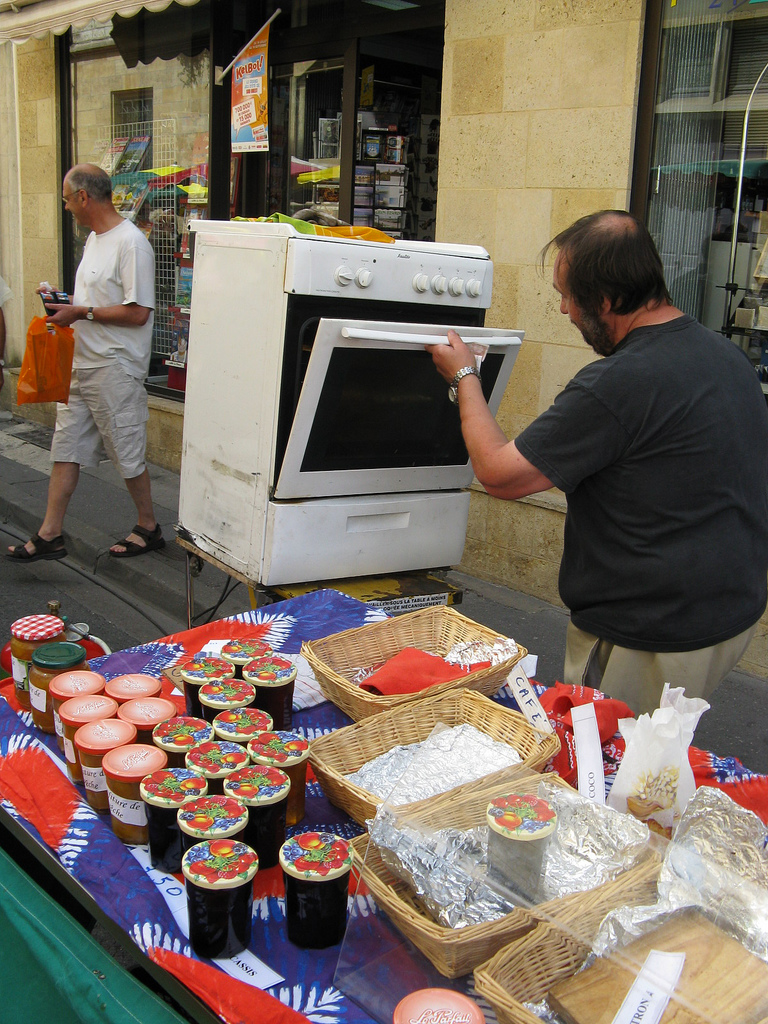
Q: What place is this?
A: It is a sidewalk.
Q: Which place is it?
A: It is a sidewalk.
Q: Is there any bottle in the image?
A: No, there are no bottles.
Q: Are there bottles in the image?
A: No, there are no bottles.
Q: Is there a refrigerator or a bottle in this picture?
A: No, there are no bottles or refrigerators.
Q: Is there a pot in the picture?
A: No, there are no pots.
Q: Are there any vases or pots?
A: No, there are no pots or vases.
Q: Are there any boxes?
A: No, there are no boxes.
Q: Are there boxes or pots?
A: No, there are no boxes or pots.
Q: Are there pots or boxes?
A: No, there are no boxes or pots.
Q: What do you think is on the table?
A: The jar is on the table.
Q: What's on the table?
A: The jar is on the table.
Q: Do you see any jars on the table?
A: Yes, there is a jar on the table.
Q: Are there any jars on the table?
A: Yes, there is a jar on the table.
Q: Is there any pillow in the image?
A: No, there are no pillows.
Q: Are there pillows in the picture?
A: No, there are no pillows.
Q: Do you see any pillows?
A: No, there are no pillows.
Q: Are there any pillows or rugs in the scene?
A: No, there are no pillows or rugs.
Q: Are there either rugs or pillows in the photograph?
A: No, there are no pillows or rugs.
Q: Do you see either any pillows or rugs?
A: No, there are no pillows or rugs.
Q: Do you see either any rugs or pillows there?
A: No, there are no pillows or rugs.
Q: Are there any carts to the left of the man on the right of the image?
A: Yes, there is a cart to the left of the man.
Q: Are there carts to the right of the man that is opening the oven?
A: No, the cart is to the left of the man.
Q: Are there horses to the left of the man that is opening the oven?
A: No, there is a cart to the left of the man.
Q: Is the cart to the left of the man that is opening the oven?
A: Yes, the cart is to the left of the man.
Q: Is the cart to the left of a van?
A: No, the cart is to the left of the man.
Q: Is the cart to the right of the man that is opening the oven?
A: No, the cart is to the left of the man.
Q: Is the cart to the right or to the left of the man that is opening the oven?
A: The cart is to the left of the man.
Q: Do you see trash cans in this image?
A: No, there are no trash cans.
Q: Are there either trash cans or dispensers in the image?
A: No, there are no trash cans or dispensers.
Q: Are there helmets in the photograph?
A: No, there are no helmets.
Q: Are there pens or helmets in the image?
A: No, there are no helmets or pens.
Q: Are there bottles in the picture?
A: No, there are no bottles.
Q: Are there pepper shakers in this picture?
A: No, there are no pepper shakers.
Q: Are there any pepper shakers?
A: No, there are no pepper shakers.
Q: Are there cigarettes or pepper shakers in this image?
A: No, there are no pepper shakers or cigarettes.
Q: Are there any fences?
A: No, there are no fences.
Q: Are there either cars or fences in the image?
A: No, there are no fences or cars.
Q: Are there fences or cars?
A: No, there are no fences or cars.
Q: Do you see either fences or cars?
A: No, there are no fences or cars.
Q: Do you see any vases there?
A: No, there are no vases.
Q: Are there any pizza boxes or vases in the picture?
A: No, there are no vases or pizza boxes.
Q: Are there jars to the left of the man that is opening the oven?
A: Yes, there is a jar to the left of the man.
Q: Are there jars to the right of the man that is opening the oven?
A: No, the jar is to the left of the man.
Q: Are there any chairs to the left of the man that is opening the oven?
A: No, there is a jar to the left of the man.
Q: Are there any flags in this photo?
A: Yes, there is a flag.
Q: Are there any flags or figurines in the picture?
A: Yes, there is a flag.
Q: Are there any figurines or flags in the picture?
A: Yes, there is a flag.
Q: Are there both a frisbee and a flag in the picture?
A: No, there is a flag but no frisbees.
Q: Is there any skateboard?
A: No, there are no skateboards.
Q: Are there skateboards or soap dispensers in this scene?
A: No, there are no skateboards or soap dispensers.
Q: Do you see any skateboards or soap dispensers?
A: No, there are no skateboards or soap dispensers.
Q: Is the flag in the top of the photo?
A: Yes, the flag is in the top of the image.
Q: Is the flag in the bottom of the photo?
A: No, the flag is in the top of the image.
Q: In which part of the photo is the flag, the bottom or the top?
A: The flag is in the top of the image.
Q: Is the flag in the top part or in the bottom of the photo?
A: The flag is in the top of the image.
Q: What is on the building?
A: The flag is on the building.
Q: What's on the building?
A: The flag is on the building.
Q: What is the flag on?
A: The flag is on the building.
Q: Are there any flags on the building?
A: Yes, there is a flag on the building.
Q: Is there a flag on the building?
A: Yes, there is a flag on the building.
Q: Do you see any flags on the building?
A: Yes, there is a flag on the building.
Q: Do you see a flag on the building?
A: Yes, there is a flag on the building.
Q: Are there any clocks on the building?
A: No, there is a flag on the building.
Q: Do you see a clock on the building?
A: No, there is a flag on the building.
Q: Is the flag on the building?
A: Yes, the flag is on the building.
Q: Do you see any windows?
A: Yes, there is a window.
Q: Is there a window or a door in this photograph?
A: Yes, there is a window.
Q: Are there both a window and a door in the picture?
A: Yes, there are both a window and a door.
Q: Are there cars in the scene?
A: No, there are no cars.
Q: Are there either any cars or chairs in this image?
A: No, there are no cars or chairs.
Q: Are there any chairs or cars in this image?
A: No, there are no cars or chairs.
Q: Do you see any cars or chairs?
A: No, there are no cars or chairs.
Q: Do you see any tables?
A: Yes, there is a table.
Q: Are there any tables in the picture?
A: Yes, there is a table.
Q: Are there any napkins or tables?
A: Yes, there is a table.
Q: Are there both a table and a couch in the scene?
A: No, there is a table but no couches.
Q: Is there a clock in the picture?
A: No, there are no clocks.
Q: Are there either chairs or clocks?
A: No, there are no clocks or chairs.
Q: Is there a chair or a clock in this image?
A: No, there are no clocks or chairs.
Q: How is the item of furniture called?
A: The piece of furniture is a table.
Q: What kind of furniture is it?
A: The piece of furniture is a table.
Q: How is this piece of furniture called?
A: This is a table.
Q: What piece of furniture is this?
A: This is a table.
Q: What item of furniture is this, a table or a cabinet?
A: This is a table.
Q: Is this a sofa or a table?
A: This is a table.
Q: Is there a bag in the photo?
A: Yes, there is a bag.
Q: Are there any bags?
A: Yes, there is a bag.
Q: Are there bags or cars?
A: Yes, there is a bag.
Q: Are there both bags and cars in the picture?
A: No, there is a bag but no cars.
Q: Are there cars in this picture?
A: No, there are no cars.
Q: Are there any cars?
A: No, there are no cars.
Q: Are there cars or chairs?
A: No, there are no cars or chairs.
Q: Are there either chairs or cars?
A: No, there are no cars or chairs.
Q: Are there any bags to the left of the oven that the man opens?
A: Yes, there is a bag to the left of the oven.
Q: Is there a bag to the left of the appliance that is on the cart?
A: Yes, there is a bag to the left of the oven.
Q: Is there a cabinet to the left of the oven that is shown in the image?
A: No, there is a bag to the left of the oven.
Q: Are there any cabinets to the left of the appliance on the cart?
A: No, there is a bag to the left of the oven.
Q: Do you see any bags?
A: Yes, there is a bag.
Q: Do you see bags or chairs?
A: Yes, there is a bag.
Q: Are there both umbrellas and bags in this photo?
A: No, there is a bag but no umbrellas.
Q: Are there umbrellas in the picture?
A: No, there are no umbrellas.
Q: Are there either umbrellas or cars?
A: No, there are no umbrellas or cars.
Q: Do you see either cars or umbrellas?
A: No, there are no umbrellas or cars.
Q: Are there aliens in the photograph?
A: No, there are no aliens.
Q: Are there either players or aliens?
A: No, there are no aliens or players.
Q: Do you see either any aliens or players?
A: No, there are no aliens or players.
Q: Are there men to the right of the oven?
A: Yes, there is a man to the right of the oven.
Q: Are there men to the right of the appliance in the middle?
A: Yes, there is a man to the right of the oven.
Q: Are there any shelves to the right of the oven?
A: No, there is a man to the right of the oven.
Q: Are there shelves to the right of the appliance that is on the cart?
A: No, there is a man to the right of the oven.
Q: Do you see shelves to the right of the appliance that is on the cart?
A: No, there is a man to the right of the oven.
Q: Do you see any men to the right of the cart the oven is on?
A: Yes, there is a man to the right of the cart.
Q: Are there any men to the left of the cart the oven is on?
A: No, the man is to the right of the cart.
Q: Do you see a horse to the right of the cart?
A: No, there is a man to the right of the cart.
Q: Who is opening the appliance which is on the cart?
A: The man is opening the oven.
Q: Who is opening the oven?
A: The man is opening the oven.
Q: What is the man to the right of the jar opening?
A: The man is opening the oven.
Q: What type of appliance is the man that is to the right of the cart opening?
A: The man is opening the oven.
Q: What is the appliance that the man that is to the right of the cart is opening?
A: The appliance is an oven.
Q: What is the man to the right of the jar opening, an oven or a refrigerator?
A: The man is opening an oven.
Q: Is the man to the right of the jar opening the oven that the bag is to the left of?
A: Yes, the man is opening the oven.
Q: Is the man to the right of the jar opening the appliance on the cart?
A: Yes, the man is opening the oven.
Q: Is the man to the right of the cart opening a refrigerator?
A: No, the man is opening the oven.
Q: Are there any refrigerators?
A: No, there are no refrigerators.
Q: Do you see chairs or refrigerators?
A: No, there are no refrigerators or chairs.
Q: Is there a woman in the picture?
A: No, there are no women.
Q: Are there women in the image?
A: No, there are no women.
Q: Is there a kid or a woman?
A: No, there are no women or children.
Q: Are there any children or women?
A: No, there are no women or children.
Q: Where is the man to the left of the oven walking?
A: The man is walking on the side walk.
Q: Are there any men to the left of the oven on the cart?
A: Yes, there is a man to the left of the oven.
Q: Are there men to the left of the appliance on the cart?
A: Yes, there is a man to the left of the oven.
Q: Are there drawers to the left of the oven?
A: No, there is a man to the left of the oven.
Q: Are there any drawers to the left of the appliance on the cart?
A: No, there is a man to the left of the oven.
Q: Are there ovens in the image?
A: Yes, there is an oven.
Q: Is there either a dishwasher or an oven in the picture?
A: Yes, there is an oven.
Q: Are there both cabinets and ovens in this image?
A: No, there is an oven but no cabinets.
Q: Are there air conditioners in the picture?
A: No, there are no air conditioners.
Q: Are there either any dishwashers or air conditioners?
A: No, there are no air conditioners or dishwashers.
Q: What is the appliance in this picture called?
A: The appliance is an oven.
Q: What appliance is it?
A: The appliance is an oven.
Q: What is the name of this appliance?
A: That is an oven.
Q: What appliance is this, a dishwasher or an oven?
A: That is an oven.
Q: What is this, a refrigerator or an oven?
A: This is an oven.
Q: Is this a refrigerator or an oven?
A: This is an oven.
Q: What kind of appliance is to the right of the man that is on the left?
A: The appliance is an oven.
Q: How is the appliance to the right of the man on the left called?
A: The appliance is an oven.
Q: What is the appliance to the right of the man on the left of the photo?
A: The appliance is an oven.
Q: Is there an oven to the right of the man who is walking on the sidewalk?
A: Yes, there is an oven to the right of the man.